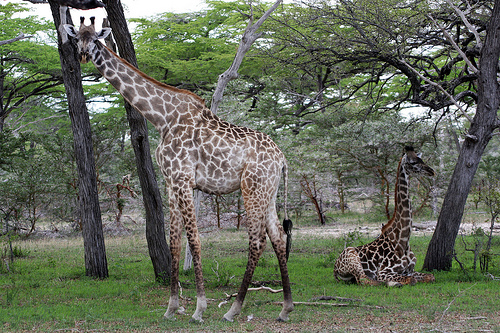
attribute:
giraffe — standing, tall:
[63, 16, 294, 324]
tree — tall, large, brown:
[48, 2, 110, 277]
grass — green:
[2, 225, 499, 333]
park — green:
[1, 1, 499, 332]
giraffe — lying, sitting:
[336, 144, 436, 288]